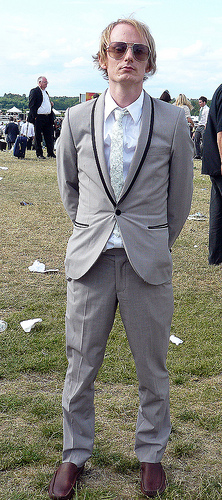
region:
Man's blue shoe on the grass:
[49, 456, 83, 497]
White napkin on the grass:
[18, 315, 44, 334]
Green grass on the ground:
[179, 300, 217, 325]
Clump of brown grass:
[6, 234, 62, 253]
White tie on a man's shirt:
[112, 110, 130, 232]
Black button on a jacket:
[114, 208, 123, 215]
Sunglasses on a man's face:
[103, 42, 149, 61]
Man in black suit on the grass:
[28, 75, 58, 160]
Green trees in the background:
[1, 91, 29, 105]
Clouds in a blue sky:
[11, 17, 73, 58]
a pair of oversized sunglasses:
[101, 37, 151, 65]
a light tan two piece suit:
[55, 86, 195, 469]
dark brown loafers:
[43, 458, 166, 498]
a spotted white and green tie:
[109, 107, 127, 196]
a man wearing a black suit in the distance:
[27, 73, 61, 162]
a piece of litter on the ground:
[25, 256, 60, 274]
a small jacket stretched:
[54, 86, 198, 285]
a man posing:
[44, 11, 195, 495]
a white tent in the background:
[4, 105, 23, 119]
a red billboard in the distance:
[75, 89, 103, 104]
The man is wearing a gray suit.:
[47, 13, 194, 497]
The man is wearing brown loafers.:
[30, 444, 178, 496]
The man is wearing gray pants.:
[33, 255, 194, 459]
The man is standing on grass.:
[28, 310, 209, 496]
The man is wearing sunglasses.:
[98, 37, 162, 61]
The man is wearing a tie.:
[100, 105, 129, 187]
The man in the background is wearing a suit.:
[14, 58, 58, 160]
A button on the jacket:
[107, 205, 125, 219]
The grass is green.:
[7, 337, 56, 374]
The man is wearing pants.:
[26, 108, 57, 161]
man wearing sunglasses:
[94, 38, 170, 78]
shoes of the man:
[37, 448, 210, 498]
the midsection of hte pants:
[79, 224, 161, 291]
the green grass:
[11, 355, 69, 462]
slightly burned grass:
[8, 446, 30, 461]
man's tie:
[112, 109, 141, 194]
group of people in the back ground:
[13, 62, 46, 164]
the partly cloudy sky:
[143, 6, 201, 76]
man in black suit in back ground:
[23, 81, 61, 170]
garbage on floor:
[11, 231, 75, 406]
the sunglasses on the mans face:
[105, 40, 153, 62]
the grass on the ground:
[3, 151, 219, 496]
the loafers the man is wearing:
[52, 455, 164, 498]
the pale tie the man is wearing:
[111, 109, 126, 237]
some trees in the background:
[2, 89, 75, 108]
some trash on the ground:
[0, 317, 38, 331]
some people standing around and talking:
[157, 87, 207, 162]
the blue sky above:
[3, 2, 219, 88]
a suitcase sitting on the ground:
[11, 132, 24, 157]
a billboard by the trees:
[78, 89, 95, 102]